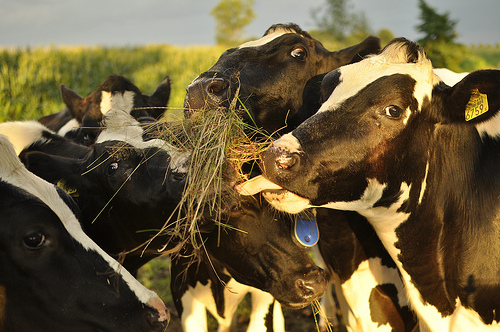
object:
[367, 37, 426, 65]
hair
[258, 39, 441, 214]
head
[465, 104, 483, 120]
number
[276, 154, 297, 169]
nose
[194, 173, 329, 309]
cow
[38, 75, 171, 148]
cows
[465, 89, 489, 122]
tag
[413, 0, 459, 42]
evergreen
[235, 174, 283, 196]
tongue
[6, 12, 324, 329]
blue tent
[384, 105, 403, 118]
eye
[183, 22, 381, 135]
cows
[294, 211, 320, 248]
blue tag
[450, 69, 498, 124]
ear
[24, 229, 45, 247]
eye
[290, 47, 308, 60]
eye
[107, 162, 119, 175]
eye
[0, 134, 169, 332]
cow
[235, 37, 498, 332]
cow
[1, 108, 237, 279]
cow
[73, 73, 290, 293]
hay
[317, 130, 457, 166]
fur